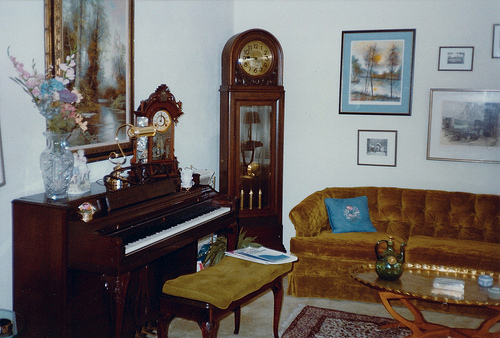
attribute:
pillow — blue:
[320, 193, 376, 232]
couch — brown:
[287, 165, 496, 313]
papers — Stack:
[225, 241, 300, 266]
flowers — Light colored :
[6, 45, 88, 131]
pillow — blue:
[323, 191, 376, 237]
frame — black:
[41, 0, 143, 162]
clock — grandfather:
[215, 27, 289, 252]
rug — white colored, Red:
[277, 297, 429, 336]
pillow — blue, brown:
[325, 188, 404, 250]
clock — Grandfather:
[238, 40, 272, 80]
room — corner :
[2, 0, 491, 337]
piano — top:
[9, 178, 237, 338]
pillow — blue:
[326, 194, 371, 235]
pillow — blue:
[310, 189, 411, 243]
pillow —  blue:
[314, 190, 379, 237]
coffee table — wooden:
[350, 260, 498, 336]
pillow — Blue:
[311, 200, 392, 262]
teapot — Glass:
[375, 235, 407, 280]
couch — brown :
[288, 180, 498, 301]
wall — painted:
[276, 16, 494, 232]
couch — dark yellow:
[283, 176, 493, 316]